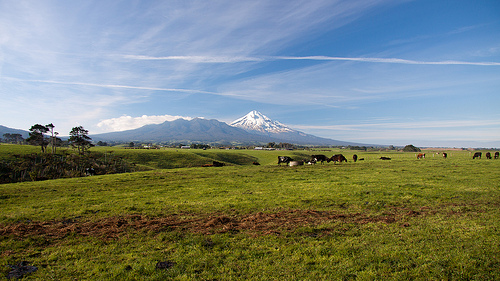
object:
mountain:
[114, 106, 306, 137]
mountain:
[82, 108, 311, 134]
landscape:
[54, 172, 467, 274]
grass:
[108, 167, 360, 192]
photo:
[4, 3, 463, 279]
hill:
[0, 145, 259, 187]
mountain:
[57, 112, 295, 152]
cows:
[275, 150, 356, 171]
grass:
[4, 147, 498, 278]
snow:
[229, 107, 289, 136]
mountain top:
[225, 107, 295, 134]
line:
[103, 53, 499, 70]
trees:
[25, 120, 93, 153]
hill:
[2, 144, 252, 185]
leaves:
[31, 123, 91, 143]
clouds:
[3, 3, 497, 145]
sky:
[0, 3, 497, 147]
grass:
[0, 198, 495, 251]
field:
[8, 147, 494, 278]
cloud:
[40, 42, 229, 98]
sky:
[1, 2, 487, 170]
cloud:
[61, 57, 201, 105]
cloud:
[76, 54, 245, 105]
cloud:
[61, 46, 217, 123]